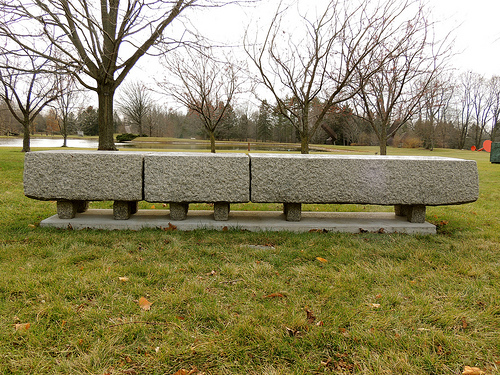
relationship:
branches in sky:
[245, 27, 347, 106] [246, 15, 258, 74]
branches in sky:
[245, 27, 347, 106] [255, 0, 280, 67]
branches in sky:
[245, 27, 347, 106] [6, 2, 497, 112]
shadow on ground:
[289, 208, 400, 237] [255, 284, 355, 352]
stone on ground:
[22, 148, 479, 233] [15, 296, 446, 363]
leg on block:
[272, 177, 314, 229] [23, 142, 480, 233]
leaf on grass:
[0, 223, 500, 375] [2, 135, 499, 374]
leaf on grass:
[284, 303, 319, 337] [2, 135, 499, 374]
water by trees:
[0, 135, 357, 152] [0, 0, 194, 152]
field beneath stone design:
[1, 132, 496, 373] [24, 149, 481, 236]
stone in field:
[22, 148, 479, 233] [1, 132, 496, 373]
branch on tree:
[118, 5, 193, 86] [0, 1, 206, 152]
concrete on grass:
[21, 149, 478, 235] [2, 135, 499, 374]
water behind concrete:
[0, 130, 367, 157] [23, 147, 484, 211]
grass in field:
[0, 135, 498, 375] [0, 219, 495, 372]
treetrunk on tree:
[298, 103, 313, 154] [265, 17, 352, 124]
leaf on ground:
[0, 223, 500, 375] [1, 128, 495, 373]